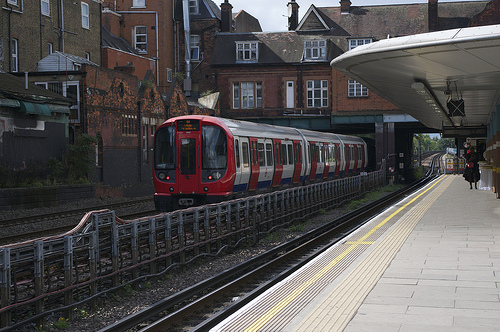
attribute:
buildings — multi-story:
[3, 1, 485, 186]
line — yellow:
[243, 172, 446, 329]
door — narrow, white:
[285, 81, 295, 109]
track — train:
[135, 169, 439, 330]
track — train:
[0, 195, 155, 240]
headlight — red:
[206, 172, 214, 182]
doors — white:
[235, 134, 370, 177]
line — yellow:
[321, 200, 384, 286]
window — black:
[279, 76, 297, 88]